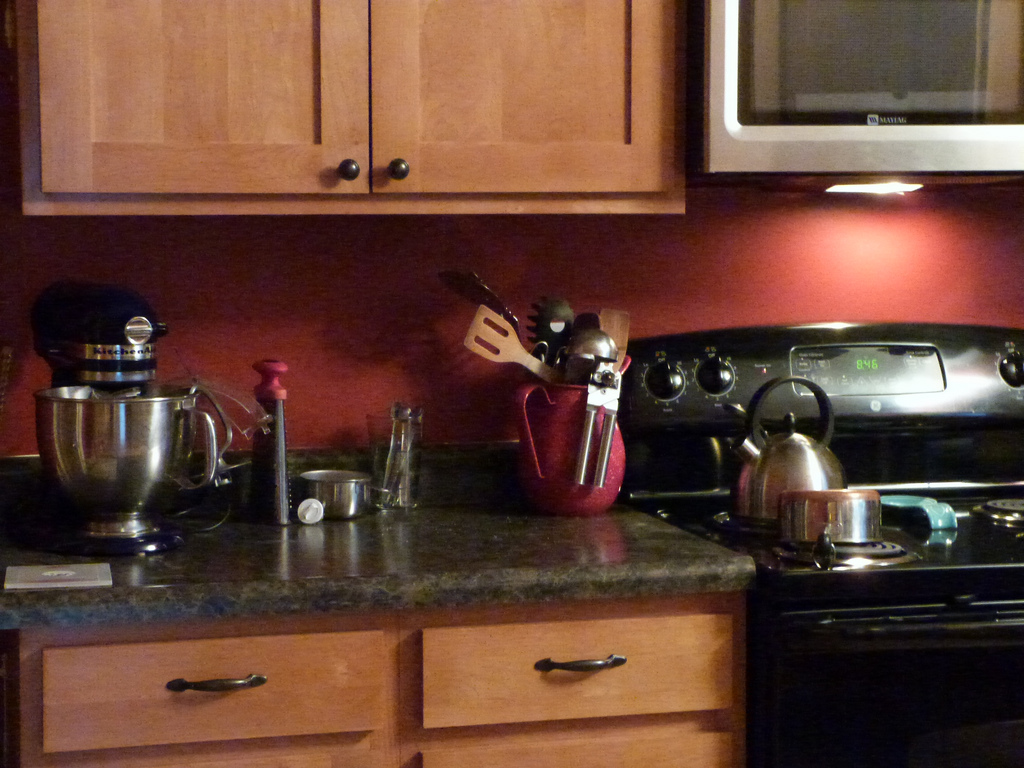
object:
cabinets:
[0, 576, 745, 768]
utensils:
[430, 258, 526, 341]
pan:
[766, 473, 925, 572]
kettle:
[710, 356, 855, 551]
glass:
[367, 430, 433, 517]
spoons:
[379, 400, 403, 502]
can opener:
[562, 332, 640, 500]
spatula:
[453, 298, 570, 385]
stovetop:
[622, 306, 1023, 591]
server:
[434, 262, 645, 487]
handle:
[529, 635, 639, 683]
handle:
[154, 657, 275, 703]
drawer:
[28, 598, 414, 768]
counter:
[0, 426, 769, 732]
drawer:
[401, 584, 749, 748]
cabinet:
[0, 0, 698, 226]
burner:
[756, 533, 926, 577]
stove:
[614, 307, 1024, 767]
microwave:
[676, 0, 1024, 208]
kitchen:
[0, 6, 1013, 768]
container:
[486, 356, 642, 527]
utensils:
[517, 279, 585, 378]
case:
[0, 551, 120, 598]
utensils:
[591, 284, 643, 385]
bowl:
[0, 272, 231, 558]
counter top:
[0, 453, 769, 638]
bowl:
[285, 446, 384, 529]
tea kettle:
[709, 363, 865, 543]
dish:
[871, 485, 967, 541]